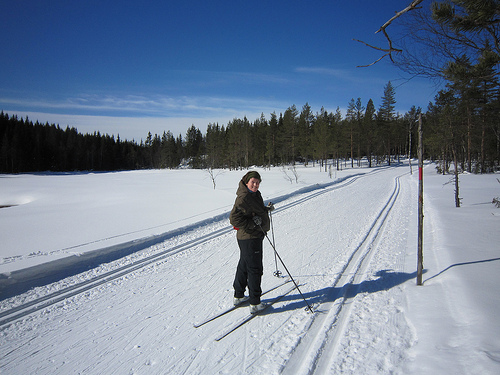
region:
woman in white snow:
[217, 165, 287, 293]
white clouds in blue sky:
[70, 43, 135, 90]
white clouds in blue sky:
[212, 25, 256, 49]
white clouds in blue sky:
[78, 89, 128, 120]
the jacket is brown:
[226, 183, 281, 253]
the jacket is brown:
[223, 176, 276, 247]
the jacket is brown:
[228, 182, 267, 252]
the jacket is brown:
[226, 188, 271, 252]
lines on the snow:
[305, 196, 385, 370]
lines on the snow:
[309, 215, 384, 365]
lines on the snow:
[290, 229, 388, 374]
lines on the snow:
[286, 220, 368, 373]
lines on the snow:
[319, 230, 389, 373]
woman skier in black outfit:
[218, 168, 266, 308]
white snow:
[91, 211, 176, 286]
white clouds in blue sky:
[35, 61, 95, 106]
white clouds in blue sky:
[78, 55, 125, 90]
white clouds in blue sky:
[107, 102, 161, 149]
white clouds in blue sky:
[185, 49, 226, 90]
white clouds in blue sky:
[142, 22, 202, 62]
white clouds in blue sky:
[301, 26, 342, 64]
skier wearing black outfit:
[224, 159, 275, 287]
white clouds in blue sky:
[82, 61, 119, 99]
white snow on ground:
[87, 262, 147, 322]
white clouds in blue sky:
[32, 13, 107, 47]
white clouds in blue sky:
[57, 86, 134, 121]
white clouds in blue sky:
[148, 48, 186, 70]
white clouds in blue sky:
[120, 108, 152, 128]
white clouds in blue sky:
[231, 9, 272, 51]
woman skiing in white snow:
[230, 159, 282, 299]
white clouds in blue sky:
[24, 26, 64, 53]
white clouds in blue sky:
[72, 13, 102, 43]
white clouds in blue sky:
[45, 69, 67, 89]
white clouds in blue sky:
[48, 36, 110, 64]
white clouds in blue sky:
[64, 69, 109, 104]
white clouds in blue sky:
[227, 56, 285, 100]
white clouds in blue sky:
[311, 23, 332, 51]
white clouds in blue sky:
[210, 32, 288, 102]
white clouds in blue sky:
[130, 22, 201, 74]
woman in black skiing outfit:
[208, 165, 278, 333]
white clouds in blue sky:
[301, 13, 329, 53]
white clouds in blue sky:
[180, 59, 197, 70]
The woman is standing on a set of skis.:
[193, 163, 306, 345]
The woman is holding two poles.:
[259, 199, 321, 315]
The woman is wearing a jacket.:
[231, 185, 271, 240]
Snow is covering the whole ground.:
[0, 168, 499, 373]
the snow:
[348, 310, 390, 345]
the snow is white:
[366, 335, 403, 372]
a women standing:
[233, 172, 276, 295]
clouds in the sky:
[131, 83, 190, 121]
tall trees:
[254, 116, 310, 146]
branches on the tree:
[373, 15, 426, 82]